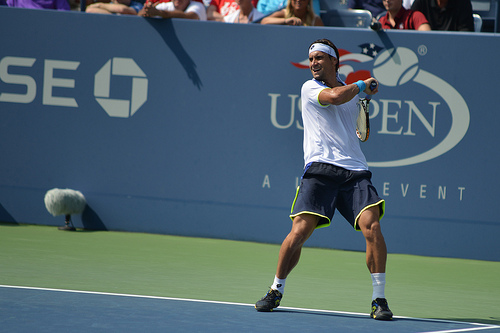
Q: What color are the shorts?
A: Blue.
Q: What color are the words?
A: White.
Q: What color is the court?
A: Blue.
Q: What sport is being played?
A: Tennis.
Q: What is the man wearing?
A: Shorts.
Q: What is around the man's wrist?
A: A blue wristband.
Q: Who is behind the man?
A: Fans.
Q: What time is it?
A: Afternoon.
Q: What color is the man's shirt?
A: White.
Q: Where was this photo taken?
A: At a tennis game.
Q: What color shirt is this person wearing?
A: White.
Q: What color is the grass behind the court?
A: Green.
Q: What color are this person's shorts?
A: Black with yellow lining.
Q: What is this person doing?
A: Playing tennis.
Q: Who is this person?
A: A tennis player.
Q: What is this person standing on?
A: A tennis court.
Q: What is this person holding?
A: A tennis racket.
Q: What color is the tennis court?
A: Blue.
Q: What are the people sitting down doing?
A: Spectating the event.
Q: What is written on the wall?
A: The name of the event.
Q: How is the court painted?
A: In blue and white.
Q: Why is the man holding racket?
A: He's in tennis tournament.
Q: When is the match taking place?
A: During the afternoon.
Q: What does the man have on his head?
A: Sweatband.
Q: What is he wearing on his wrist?
A: Blue wristband.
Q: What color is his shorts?
A: Blue.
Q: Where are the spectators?
A: In the stands.